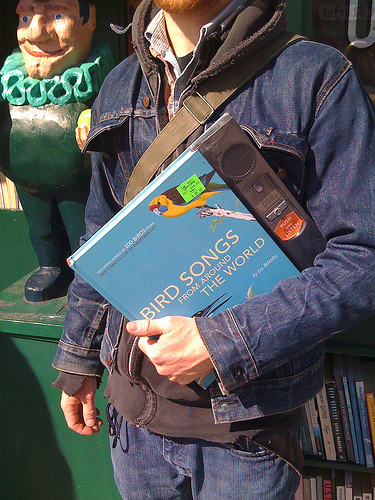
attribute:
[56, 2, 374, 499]
person — blue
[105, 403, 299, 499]
jeans — blue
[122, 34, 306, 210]
bag — brown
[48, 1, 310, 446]
shirt — brown, black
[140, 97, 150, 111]
button — orange, metal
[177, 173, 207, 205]
tag — green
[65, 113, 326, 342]
book — blue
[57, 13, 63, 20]
eyes — blue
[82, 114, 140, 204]
pocket — unbuttoned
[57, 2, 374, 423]
jacket — blue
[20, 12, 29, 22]
eyes — blue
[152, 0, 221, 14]
beard — orange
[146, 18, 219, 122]
collar — open